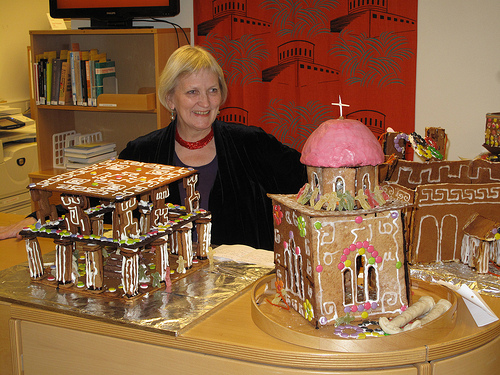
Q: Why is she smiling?
A: She's happy.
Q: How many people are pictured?
A: One.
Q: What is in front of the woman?
A: Gingerbread house.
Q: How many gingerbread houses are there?
A: Three.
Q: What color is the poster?
A: Red.